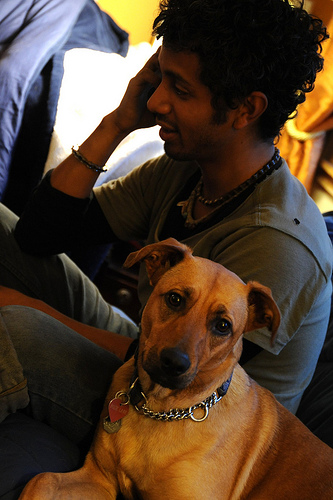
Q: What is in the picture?
A: A dog.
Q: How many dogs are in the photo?
A: One.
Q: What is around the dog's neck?
A: A collar.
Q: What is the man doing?
A: Talking on the phone.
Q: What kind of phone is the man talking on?
A: Cell phone.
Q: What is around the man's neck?
A: A necklace.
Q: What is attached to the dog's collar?
A: Name tag.